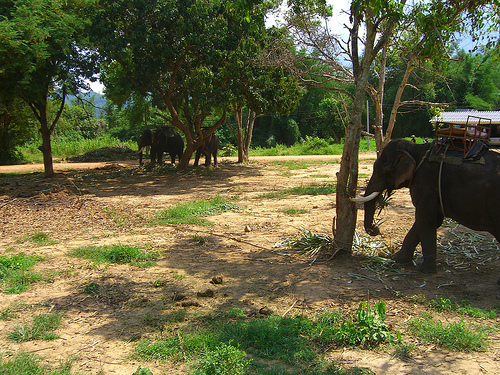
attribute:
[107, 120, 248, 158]
elephants — standing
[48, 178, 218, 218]
dirt — brown, dried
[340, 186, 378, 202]
tusks — curved, white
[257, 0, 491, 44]
sky — bright, blue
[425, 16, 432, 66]
leaves — narrow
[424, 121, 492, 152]
bench — empty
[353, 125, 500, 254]
elephant — moving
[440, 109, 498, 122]
roof — gray, metal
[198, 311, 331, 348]
grass — green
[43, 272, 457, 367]
ground — light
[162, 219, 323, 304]
shadow — tree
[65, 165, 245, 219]
area — sandy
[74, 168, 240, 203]
shadow — trees